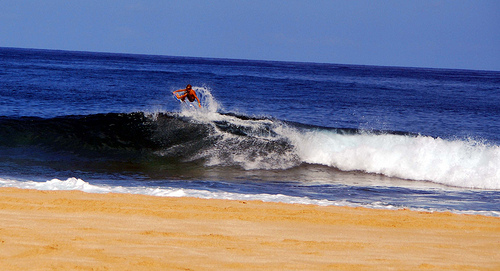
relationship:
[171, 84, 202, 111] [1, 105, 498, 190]
man on wave